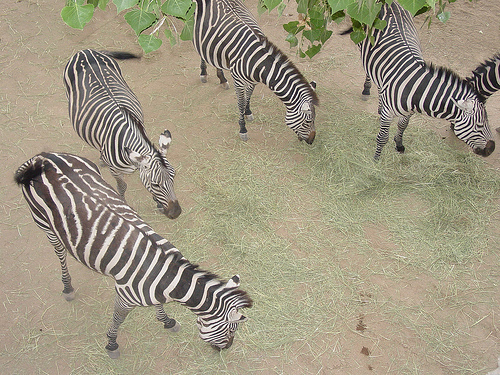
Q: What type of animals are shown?
A: Zebras.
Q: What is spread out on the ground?
A: Hay.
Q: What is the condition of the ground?
A: Bare.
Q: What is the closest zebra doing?
A: Eating.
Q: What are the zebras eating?
A: Hay.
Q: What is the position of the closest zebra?
A: Standing.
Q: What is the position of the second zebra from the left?
A: Standing.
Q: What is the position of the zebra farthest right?
A: Standing.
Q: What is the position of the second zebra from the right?
A: Standing.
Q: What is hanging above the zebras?
A: Tree leaves.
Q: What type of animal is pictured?
A: Zebra.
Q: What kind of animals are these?
A: Zebras.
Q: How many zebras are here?
A: Five.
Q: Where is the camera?
A: Above the animals.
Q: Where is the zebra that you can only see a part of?
A: On the far right.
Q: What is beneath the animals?
A: Dirt and strrewn grass.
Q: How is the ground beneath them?
A: Dry.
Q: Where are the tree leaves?
A: At the top of the photograph.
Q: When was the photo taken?
A: On a cloudy day, as evidenced by the lack of shadows.